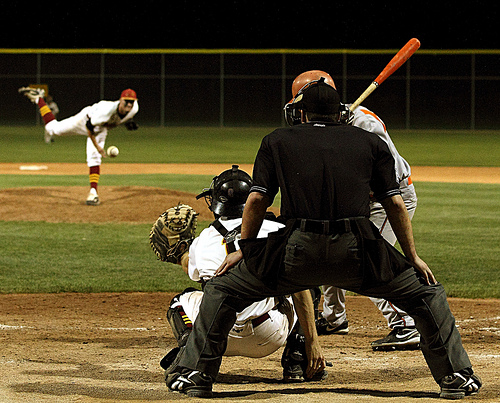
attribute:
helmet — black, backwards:
[208, 167, 255, 218]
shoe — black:
[166, 361, 221, 396]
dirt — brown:
[0, 289, 499, 402]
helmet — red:
[280, 69, 340, 111]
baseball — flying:
[108, 146, 119, 159]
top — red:
[373, 36, 431, 89]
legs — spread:
[169, 226, 469, 397]